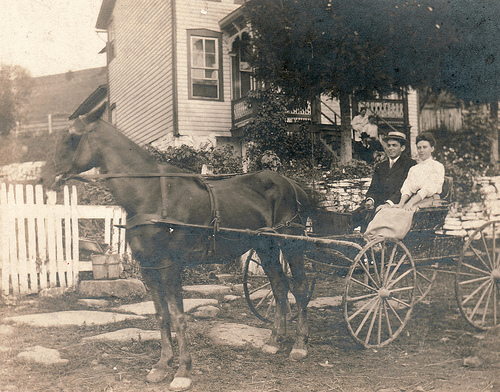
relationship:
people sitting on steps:
[348, 104, 380, 155] [305, 117, 351, 159]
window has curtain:
[190, 32, 217, 97] [192, 37, 217, 95]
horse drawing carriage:
[36, 106, 335, 390] [239, 126, 499, 363]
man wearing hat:
[347, 128, 415, 231] [380, 129, 411, 141]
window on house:
[190, 32, 217, 97] [91, 0, 496, 152]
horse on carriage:
[36, 106, 335, 390] [249, 204, 498, 334]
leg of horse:
[273, 207, 320, 364] [36, 106, 335, 390]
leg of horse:
[247, 227, 291, 357] [36, 106, 335, 390]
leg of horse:
[155, 241, 199, 390] [36, 106, 335, 390]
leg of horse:
[128, 234, 174, 390] [36, 106, 335, 390]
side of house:
[107, 0, 175, 143] [91, 0, 496, 152]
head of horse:
[36, 103, 108, 190] [36, 106, 335, 390]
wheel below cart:
[345, 235, 420, 370] [239, 194, 499, 351]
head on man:
[383, 135, 407, 161] [352, 128, 417, 235]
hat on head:
[380, 130, 411, 147] [383, 135, 407, 161]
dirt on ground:
[338, 353, 463, 387] [3, 268, 493, 390]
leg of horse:
[258, 246, 289, 356] [36, 106, 335, 390]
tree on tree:
[227, 6, 498, 171] [235, 0, 390, 168]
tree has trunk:
[227, 6, 498, 171] [341, 99, 352, 159]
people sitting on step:
[348, 104, 380, 155] [316, 123, 370, 160]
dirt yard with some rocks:
[2, 262, 483, 384] [3, 295, 141, 369]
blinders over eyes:
[56, 114, 113, 146] [57, 125, 80, 150]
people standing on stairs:
[348, 104, 380, 155] [278, 82, 415, 194]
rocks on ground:
[11, 305, 171, 374] [4, 254, 484, 390]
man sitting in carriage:
[347, 128, 415, 231] [243, 174, 484, 348]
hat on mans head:
[380, 130, 411, 147] [316, 117, 488, 184]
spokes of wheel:
[462, 266, 480, 295] [454, 218, 484, 334]